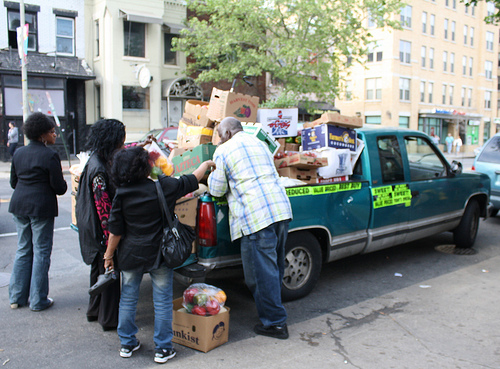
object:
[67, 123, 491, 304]
truck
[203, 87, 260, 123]
box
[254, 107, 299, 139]
box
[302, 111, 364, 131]
box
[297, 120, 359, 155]
box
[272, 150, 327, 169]
box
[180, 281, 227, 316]
bag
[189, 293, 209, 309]
produce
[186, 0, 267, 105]
building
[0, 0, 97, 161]
building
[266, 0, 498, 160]
building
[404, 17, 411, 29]
window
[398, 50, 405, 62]
window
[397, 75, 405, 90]
window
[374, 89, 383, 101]
window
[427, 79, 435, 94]
window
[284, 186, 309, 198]
black print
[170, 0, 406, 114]
tree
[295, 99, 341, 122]
building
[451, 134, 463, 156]
people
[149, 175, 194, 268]
purse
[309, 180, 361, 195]
stickers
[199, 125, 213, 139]
food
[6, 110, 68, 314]
lady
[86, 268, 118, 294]
sandles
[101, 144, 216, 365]
lady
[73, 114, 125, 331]
lady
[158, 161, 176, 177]
vegetables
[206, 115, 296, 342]
man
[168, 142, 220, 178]
cargo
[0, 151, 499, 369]
street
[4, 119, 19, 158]
individual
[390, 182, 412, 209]
stickers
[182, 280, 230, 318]
visible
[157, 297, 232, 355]
box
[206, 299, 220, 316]
vegetables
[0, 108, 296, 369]
talking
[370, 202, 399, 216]
blue-green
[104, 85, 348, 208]
empty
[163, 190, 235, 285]
back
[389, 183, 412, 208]
flourescent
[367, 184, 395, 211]
advertisement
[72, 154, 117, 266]
sleeveless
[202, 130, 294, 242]
plaid jacket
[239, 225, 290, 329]
jeans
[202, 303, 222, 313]
red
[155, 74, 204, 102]
canopy